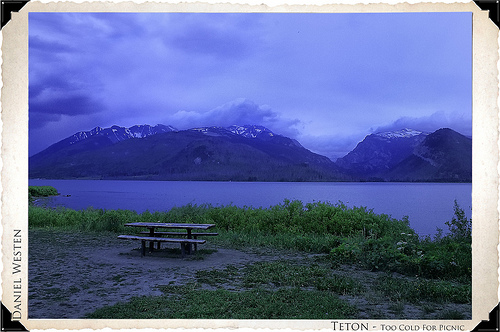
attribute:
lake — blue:
[29, 167, 474, 254]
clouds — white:
[29, 18, 473, 128]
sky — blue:
[29, 12, 469, 129]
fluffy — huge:
[77, 101, 352, 218]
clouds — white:
[300, 134, 365, 151]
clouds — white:
[29, 32, 84, 52]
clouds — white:
[30, 86, 108, 114]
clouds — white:
[163, 10, 268, 67]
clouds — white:
[171, 99, 301, 135]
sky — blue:
[29, 11, 470, 158]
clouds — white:
[354, 109, 471, 138]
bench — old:
[118, 220, 218, 253]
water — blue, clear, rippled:
[235, 187, 482, 221]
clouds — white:
[295, 76, 309, 87]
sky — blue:
[29, 10, 473, 180]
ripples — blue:
[75, 185, 172, 200]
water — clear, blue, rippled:
[30, 177, 472, 237]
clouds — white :
[133, 34, 218, 106]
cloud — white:
[160, 95, 303, 137]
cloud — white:
[376, 107, 473, 133]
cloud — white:
[29, 26, 86, 56]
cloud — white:
[166, 18, 259, 60]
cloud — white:
[29, 82, 111, 117]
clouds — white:
[136, 12, 258, 62]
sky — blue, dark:
[28, 12, 473, 143]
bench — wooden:
[105, 200, 268, 288]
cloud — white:
[174, 98, 303, 140]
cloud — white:
[146, 90, 308, 141]